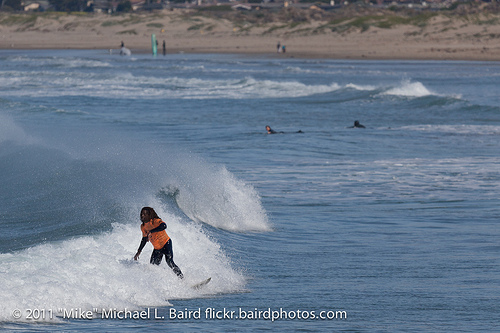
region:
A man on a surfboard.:
[128, 195, 217, 294]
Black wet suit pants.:
[149, 242, 188, 287]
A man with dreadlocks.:
[133, 200, 162, 225]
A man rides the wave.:
[70, 195, 257, 307]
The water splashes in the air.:
[33, 103, 142, 208]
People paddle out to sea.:
[258, 105, 413, 145]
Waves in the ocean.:
[194, 50, 440, 104]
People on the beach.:
[104, 29, 293, 59]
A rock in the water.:
[116, 44, 133, 60]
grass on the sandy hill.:
[294, 20, 459, 44]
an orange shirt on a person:
[141, 213, 169, 254]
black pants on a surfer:
[146, 235, 181, 281]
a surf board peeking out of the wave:
[197, 270, 214, 290]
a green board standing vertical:
[146, 30, 161, 59]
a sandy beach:
[0, 29, 498, 53]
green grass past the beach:
[189, 7, 260, 33]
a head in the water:
[262, 122, 279, 133]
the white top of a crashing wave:
[389, 79, 432, 97]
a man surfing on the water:
[113, 201, 221, 294]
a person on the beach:
[274, 38, 283, 53]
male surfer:
[133, 201, 198, 289]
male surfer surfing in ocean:
[131, 208, 181, 276]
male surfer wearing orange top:
[136, 220, 171, 243]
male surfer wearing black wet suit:
[147, 252, 182, 268]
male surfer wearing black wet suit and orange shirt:
[135, 221, 180, 267]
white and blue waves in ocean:
[29, 232, 119, 304]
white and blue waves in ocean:
[187, 171, 260, 230]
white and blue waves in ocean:
[49, 106, 151, 149]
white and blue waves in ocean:
[132, 59, 229, 104]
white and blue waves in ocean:
[274, 76, 408, 103]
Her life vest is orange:
[141, 223, 178, 251]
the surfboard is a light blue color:
[146, 33, 173, 64]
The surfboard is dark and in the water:
[178, 268, 240, 296]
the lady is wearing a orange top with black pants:
[125, 200, 197, 295]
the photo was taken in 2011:
[12, 298, 77, 318]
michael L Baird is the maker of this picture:
[59, 302, 360, 322]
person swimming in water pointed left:
[254, 121, 329, 143]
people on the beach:
[266, 32, 306, 55]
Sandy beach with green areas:
[333, 22, 431, 54]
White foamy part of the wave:
[11, 267, 124, 309]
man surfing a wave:
[91, 198, 224, 291]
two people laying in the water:
[250, 108, 390, 143]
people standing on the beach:
[267, 33, 291, 55]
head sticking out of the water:
[260, 121, 277, 134]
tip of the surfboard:
[194, 275, 217, 288]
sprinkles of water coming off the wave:
[130, 147, 205, 184]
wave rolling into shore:
[301, 66, 446, 112]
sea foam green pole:
[148, 29, 160, 56]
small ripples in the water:
[317, 156, 459, 213]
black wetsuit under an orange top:
[126, 218, 195, 283]